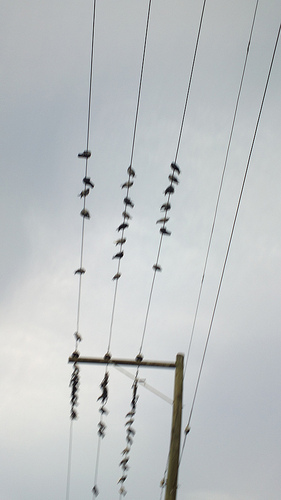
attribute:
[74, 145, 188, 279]
birds — black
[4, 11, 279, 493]
sky — grey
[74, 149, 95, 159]
bird — black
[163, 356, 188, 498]
pole — wood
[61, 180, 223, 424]
wires — black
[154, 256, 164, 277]
bird — black